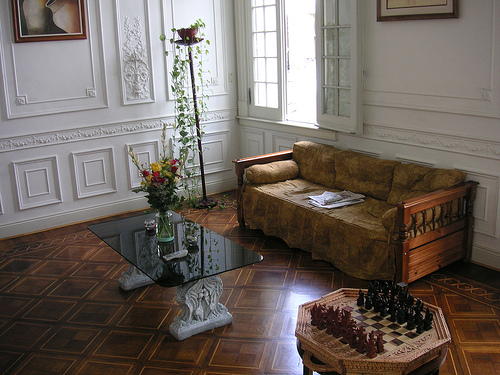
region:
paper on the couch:
[307, 188, 364, 213]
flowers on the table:
[135, 165, 180, 207]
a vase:
[150, 212, 177, 242]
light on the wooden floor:
[274, 281, 310, 307]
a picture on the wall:
[14, 8, 87, 40]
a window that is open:
[283, 40, 316, 117]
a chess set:
[302, 284, 449, 356]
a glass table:
[200, 238, 245, 268]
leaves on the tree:
[166, 65, 201, 120]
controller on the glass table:
[160, 245, 193, 262]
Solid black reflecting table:
[88, 202, 265, 283]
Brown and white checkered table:
[292, 278, 449, 373]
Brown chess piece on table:
[308, 302, 388, 360]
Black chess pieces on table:
[356, 277, 438, 333]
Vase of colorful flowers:
[120, 140, 188, 247]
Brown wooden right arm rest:
[390, 181, 481, 288]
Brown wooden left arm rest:
[233, 145, 294, 166]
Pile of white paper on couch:
[307, 183, 369, 218]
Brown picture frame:
[11, 0, 91, 41]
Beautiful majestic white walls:
[0, 0, 499, 277]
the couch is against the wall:
[229, 135, 473, 287]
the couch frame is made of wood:
[230, 136, 478, 286]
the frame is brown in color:
[402, 185, 483, 285]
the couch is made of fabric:
[249, 135, 460, 272]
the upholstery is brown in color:
[245, 133, 467, 276]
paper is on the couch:
[310, 187, 362, 209]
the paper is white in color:
[310, 187, 363, 214]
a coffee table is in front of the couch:
[88, 203, 267, 336]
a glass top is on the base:
[93, 205, 263, 290]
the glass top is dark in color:
[92, 203, 266, 293]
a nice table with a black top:
[73, 183, 298, 365]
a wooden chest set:
[289, 276, 458, 374]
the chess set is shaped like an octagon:
[291, 267, 456, 374]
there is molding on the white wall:
[2, 0, 250, 231]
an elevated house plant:
[152, 16, 239, 224]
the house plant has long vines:
[155, 15, 245, 230]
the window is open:
[236, 0, 376, 138]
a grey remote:
[155, 242, 196, 263]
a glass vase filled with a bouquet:
[130, 153, 191, 253]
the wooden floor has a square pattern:
[2, 169, 498, 373]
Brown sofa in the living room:
[231, 131, 483, 287]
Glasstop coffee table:
[78, 193, 268, 335]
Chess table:
[291, 276, 447, 373]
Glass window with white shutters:
[236, 0, 369, 137]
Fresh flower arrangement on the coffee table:
[118, 123, 235, 289]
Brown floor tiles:
[11, 255, 129, 352]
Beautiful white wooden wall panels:
[1, 4, 261, 234]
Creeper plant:
[161, 18, 238, 211]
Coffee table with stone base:
[81, 207, 268, 340]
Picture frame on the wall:
[5, 0, 105, 60]